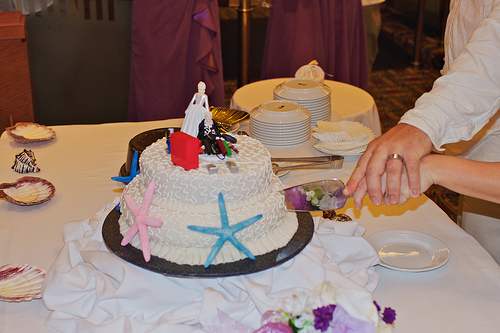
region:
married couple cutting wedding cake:
[108, 4, 498, 271]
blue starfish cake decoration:
[192, 195, 266, 264]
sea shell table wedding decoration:
[2, 175, 55, 213]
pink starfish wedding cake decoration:
[109, 187, 169, 271]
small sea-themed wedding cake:
[107, 74, 312, 279]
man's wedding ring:
[383, 149, 406, 164]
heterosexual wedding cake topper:
[168, 74, 238, 171]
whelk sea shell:
[9, 147, 43, 172]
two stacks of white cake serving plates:
[248, 76, 303, 149]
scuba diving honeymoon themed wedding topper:
[166, 79, 243, 173]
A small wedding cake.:
[97, 79, 304, 266]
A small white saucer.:
[368, 225, 448, 277]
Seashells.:
[1, 117, 54, 310]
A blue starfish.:
[187, 191, 260, 267]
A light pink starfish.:
[117, 179, 163, 261]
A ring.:
[387, 151, 402, 163]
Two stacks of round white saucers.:
[248, 77, 335, 147]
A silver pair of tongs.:
[267, 148, 345, 175]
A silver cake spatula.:
[277, 176, 362, 213]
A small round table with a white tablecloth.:
[232, 70, 379, 132]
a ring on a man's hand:
[385, 150, 407, 169]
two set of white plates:
[241, 76, 337, 148]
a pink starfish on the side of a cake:
[115, 178, 165, 268]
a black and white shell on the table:
[6, 147, 47, 180]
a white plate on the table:
[354, 224, 456, 286]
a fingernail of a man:
[384, 192, 398, 208]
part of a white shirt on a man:
[392, 0, 499, 165]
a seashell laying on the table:
[0, 168, 60, 210]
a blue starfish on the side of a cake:
[180, 190, 273, 270]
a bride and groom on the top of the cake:
[176, 71, 225, 158]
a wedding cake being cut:
[85, 70, 330, 282]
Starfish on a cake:
[113, 154, 277, 275]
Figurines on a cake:
[170, 77, 252, 173]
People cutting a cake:
[270, 128, 475, 238]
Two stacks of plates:
[251, 75, 337, 147]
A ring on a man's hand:
[382, 145, 406, 172]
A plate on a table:
[373, 222, 449, 279]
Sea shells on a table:
[3, 113, 55, 330]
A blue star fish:
[189, 190, 272, 269]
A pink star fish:
[118, 177, 168, 257]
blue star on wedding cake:
[185, 190, 263, 266]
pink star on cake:
[116, 179, 163, 263]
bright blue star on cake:
[109, 146, 141, 211]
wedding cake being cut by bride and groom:
[109, 82, 303, 269]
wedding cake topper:
[163, 77, 243, 168]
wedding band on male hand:
[384, 149, 404, 163]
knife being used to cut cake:
[271, 174, 351, 214]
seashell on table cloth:
[5, 117, 60, 145]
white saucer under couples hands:
[369, 224, 450, 275]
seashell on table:
[12, 144, 44, 176]